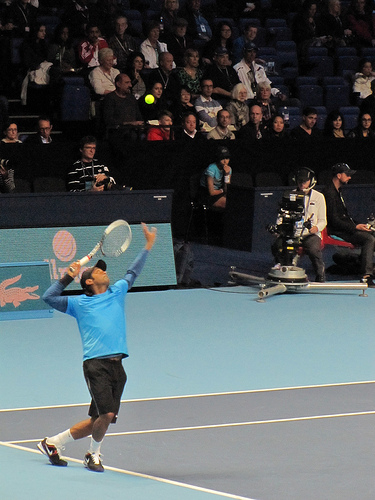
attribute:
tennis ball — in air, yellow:
[145, 94, 154, 104]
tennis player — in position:
[37, 223, 158, 474]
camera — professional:
[264, 195, 310, 265]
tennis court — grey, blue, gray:
[0, 280, 373, 499]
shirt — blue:
[39, 250, 149, 361]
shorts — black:
[83, 359, 127, 424]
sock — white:
[49, 428, 76, 449]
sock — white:
[87, 435, 104, 459]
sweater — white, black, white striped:
[67, 160, 116, 192]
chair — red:
[321, 228, 358, 272]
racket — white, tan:
[70, 219, 134, 272]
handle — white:
[70, 243, 101, 271]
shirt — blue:
[199, 164, 231, 190]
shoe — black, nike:
[37, 437, 69, 467]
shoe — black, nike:
[84, 453, 105, 473]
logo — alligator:
[0, 273, 41, 309]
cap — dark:
[81, 259, 108, 289]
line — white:
[0, 380, 374, 413]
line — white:
[2, 410, 375, 446]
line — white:
[0, 440, 252, 499]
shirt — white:
[303, 189, 326, 238]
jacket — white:
[304, 188, 326, 238]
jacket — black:
[321, 180, 356, 238]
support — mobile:
[228, 264, 369, 303]